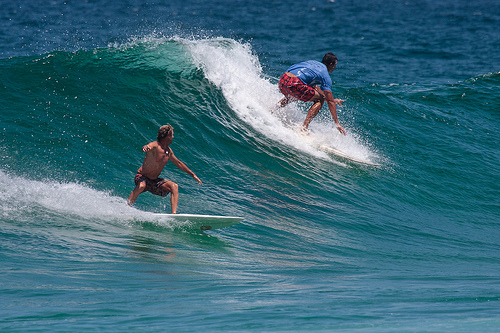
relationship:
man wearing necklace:
[124, 120, 203, 214] [160, 145, 171, 158]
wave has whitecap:
[3, 30, 391, 261] [182, 30, 390, 181]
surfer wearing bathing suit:
[267, 52, 349, 137] [276, 73, 317, 105]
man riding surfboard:
[124, 120, 203, 214] [154, 212, 247, 229]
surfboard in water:
[154, 212, 247, 229] [2, 0, 499, 331]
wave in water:
[3, 30, 391, 261] [2, 0, 499, 331]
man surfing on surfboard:
[124, 120, 203, 214] [154, 212, 247, 229]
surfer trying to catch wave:
[267, 52, 349, 137] [3, 30, 391, 261]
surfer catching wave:
[267, 52, 349, 137] [3, 30, 391, 261]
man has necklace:
[124, 120, 203, 214] [160, 145, 171, 158]